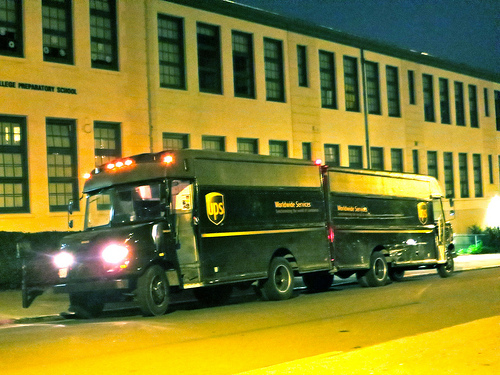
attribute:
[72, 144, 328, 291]
truck — brown, big, black, parked, dark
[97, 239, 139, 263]
lights — reflecting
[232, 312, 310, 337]
road — dark, lit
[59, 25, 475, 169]
building — tan, close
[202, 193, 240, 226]
logo — yellow